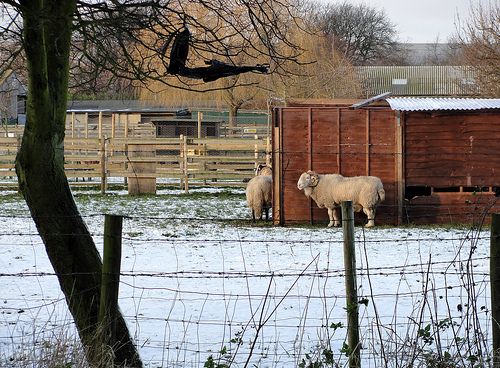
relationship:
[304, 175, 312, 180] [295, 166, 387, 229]
eye of sheep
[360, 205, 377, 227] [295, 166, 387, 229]
leg of sheep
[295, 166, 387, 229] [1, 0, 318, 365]
sheep near tree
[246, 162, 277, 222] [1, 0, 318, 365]
lamb near tree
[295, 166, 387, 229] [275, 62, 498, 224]
sheep on side of building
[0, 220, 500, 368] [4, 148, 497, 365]
snow on ground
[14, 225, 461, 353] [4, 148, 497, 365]
snow on ground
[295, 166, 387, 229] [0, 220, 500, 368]
sheep in snow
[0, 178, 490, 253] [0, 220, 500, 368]
grass poking through snow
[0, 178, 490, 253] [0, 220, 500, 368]
grass through snow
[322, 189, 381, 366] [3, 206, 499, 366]
post on fence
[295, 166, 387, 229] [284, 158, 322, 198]
sheep has head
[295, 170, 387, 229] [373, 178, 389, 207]
sheep has tail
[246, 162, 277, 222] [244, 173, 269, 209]
lamb has body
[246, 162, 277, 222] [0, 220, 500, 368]
lamb in snow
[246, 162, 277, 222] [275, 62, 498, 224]
lamb on building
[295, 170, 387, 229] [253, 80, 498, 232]
sheep side building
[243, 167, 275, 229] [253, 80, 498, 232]
sheep side building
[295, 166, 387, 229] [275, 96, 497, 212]
sheep side building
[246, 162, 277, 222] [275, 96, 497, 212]
lamb side building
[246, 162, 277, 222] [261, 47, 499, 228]
lamb side building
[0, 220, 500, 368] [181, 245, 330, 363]
snow on ground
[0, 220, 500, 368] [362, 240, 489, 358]
snow on ground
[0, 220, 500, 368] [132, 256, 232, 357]
snow on ground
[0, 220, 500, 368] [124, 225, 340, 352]
snow on ground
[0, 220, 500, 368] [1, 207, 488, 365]
snow on ground